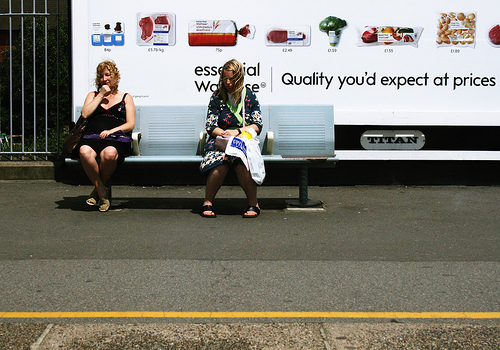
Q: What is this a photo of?
A: People sitting on a bench.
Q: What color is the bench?
A: Light blue.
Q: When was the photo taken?
A: Daytime.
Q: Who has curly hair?
A: The woman on the left.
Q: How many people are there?
A: Two.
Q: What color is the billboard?
A: White.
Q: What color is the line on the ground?
A: Yellow.